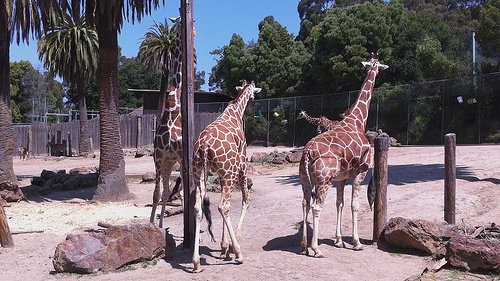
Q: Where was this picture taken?
A: Zoo.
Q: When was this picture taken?
A: Daytime.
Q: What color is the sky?
A: Blue.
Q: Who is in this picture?
A: No one.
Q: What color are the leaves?
A: Green.